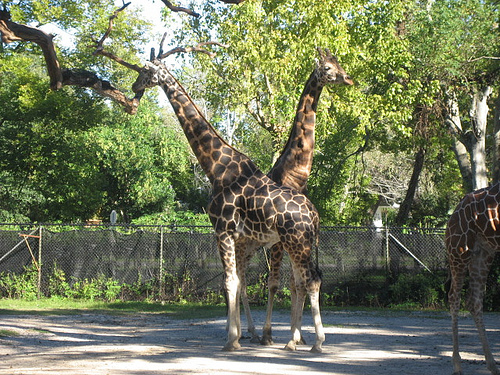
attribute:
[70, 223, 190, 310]
fence — silver, metal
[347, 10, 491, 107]
tree — close, blooming, healthy, bushy, lush, behind, green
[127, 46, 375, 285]
giraffes — watching, close, looking, skinny, big, long, tall, orange, black, standing, yellow, brown, together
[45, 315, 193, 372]
ground — white, close, brown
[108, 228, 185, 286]
metal — grey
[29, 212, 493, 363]
post — support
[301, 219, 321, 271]
tail — giraffe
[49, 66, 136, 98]
branch — tree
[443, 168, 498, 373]
giraffe — rear, end, third